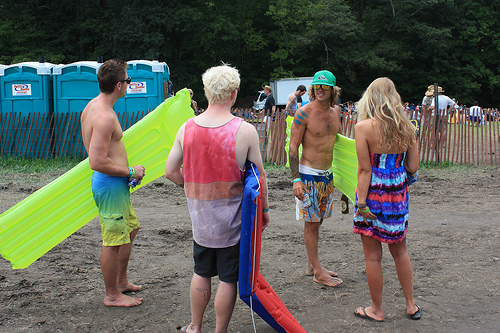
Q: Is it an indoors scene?
A: Yes, it is indoors.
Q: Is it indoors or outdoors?
A: It is indoors.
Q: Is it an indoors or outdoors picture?
A: It is indoors.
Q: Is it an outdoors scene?
A: No, it is indoors.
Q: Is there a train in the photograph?
A: No, there are no trains.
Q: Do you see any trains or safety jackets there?
A: No, there are no trains or safety jackets.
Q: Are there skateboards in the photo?
A: No, there are no skateboards.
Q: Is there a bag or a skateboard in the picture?
A: No, there are no skateboards or bags.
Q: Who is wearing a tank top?
A: The guy is wearing a tank top.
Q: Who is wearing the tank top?
A: The guy is wearing a tank top.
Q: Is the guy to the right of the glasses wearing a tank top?
A: Yes, the guy is wearing a tank top.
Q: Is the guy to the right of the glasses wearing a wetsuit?
A: No, the guy is wearing a tank top.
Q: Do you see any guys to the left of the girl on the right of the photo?
A: Yes, there is a guy to the left of the girl.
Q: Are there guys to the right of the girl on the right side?
A: No, the guy is to the left of the girl.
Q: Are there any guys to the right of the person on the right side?
A: No, the guy is to the left of the girl.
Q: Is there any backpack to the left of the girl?
A: No, there is a guy to the left of the girl.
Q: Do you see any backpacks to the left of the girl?
A: No, there is a guy to the left of the girl.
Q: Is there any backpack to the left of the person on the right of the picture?
A: No, there is a guy to the left of the girl.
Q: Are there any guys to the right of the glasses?
A: Yes, there is a guy to the right of the glasses.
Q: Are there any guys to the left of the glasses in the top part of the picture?
A: No, the guy is to the right of the glasses.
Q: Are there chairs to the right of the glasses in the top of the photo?
A: No, there is a guy to the right of the glasses.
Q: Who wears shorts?
A: The guy wears shorts.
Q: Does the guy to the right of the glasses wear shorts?
A: Yes, the guy wears shorts.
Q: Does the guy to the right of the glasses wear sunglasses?
A: No, the guy wears shorts.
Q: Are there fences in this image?
A: Yes, there is a fence.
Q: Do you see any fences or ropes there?
A: Yes, there is a fence.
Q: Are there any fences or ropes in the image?
A: Yes, there is a fence.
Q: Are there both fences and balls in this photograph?
A: No, there is a fence but no balls.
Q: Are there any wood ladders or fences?
A: Yes, there is a wood fence.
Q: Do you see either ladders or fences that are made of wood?
A: Yes, the fence is made of wood.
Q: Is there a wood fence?
A: Yes, there is a wood fence.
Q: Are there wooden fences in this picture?
A: Yes, there is a wood fence.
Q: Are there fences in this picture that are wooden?
A: Yes, there is a fence that is wooden.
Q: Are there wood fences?
A: Yes, there is a fence that is made of wood.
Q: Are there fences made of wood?
A: Yes, there is a fence that is made of wood.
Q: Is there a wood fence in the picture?
A: Yes, there is a fence that is made of wood.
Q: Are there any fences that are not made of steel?
A: Yes, there is a fence that is made of wood.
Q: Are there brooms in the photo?
A: No, there are no brooms.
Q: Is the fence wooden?
A: Yes, the fence is wooden.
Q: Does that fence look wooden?
A: Yes, the fence is wooden.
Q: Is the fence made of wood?
A: Yes, the fence is made of wood.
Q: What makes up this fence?
A: The fence is made of wood.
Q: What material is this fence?
A: The fence is made of wood.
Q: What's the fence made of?
A: The fence is made of wood.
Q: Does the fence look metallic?
A: No, the fence is wooden.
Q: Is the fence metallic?
A: No, the fence is wooden.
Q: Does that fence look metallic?
A: No, the fence is wooden.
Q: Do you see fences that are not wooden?
A: No, there is a fence but it is wooden.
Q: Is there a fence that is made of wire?
A: No, there is a fence but it is made of wood.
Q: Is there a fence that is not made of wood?
A: No, there is a fence but it is made of wood.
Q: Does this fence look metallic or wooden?
A: The fence is wooden.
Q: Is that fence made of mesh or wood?
A: The fence is made of wood.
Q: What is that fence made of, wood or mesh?
A: The fence is made of wood.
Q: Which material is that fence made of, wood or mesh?
A: The fence is made of wood.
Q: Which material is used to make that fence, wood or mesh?
A: The fence is made of wood.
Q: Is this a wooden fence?
A: Yes, this is a wooden fence.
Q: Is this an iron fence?
A: No, this is a wooden fence.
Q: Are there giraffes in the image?
A: No, there are no giraffes.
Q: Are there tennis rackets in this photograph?
A: No, there are no tennis rackets.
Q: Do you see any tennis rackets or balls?
A: No, there are no tennis rackets or balls.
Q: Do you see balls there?
A: No, there are no balls.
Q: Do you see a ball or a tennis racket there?
A: No, there are no balls or rackets.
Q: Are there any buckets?
A: No, there are no buckets.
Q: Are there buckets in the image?
A: No, there are no buckets.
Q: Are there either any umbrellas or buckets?
A: No, there are no buckets or umbrellas.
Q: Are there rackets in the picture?
A: No, there are no rackets.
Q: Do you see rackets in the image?
A: No, there are no rackets.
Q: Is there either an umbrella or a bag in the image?
A: No, there are no bags or umbrellas.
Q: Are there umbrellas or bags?
A: No, there are no bags or umbrellas.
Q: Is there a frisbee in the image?
A: No, there are no frisbees.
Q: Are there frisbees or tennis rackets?
A: No, there are no frisbees or tennis rackets.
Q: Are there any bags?
A: No, there are no bags.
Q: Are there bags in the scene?
A: No, there are no bags.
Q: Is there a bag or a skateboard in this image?
A: No, there are no bags or skateboards.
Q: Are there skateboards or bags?
A: No, there are no bags or skateboards.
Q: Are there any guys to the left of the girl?
A: Yes, there is a guy to the left of the girl.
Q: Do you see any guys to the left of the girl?
A: Yes, there is a guy to the left of the girl.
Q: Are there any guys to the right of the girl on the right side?
A: No, the guy is to the left of the girl.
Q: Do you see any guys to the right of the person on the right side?
A: No, the guy is to the left of the girl.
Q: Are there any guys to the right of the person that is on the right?
A: No, the guy is to the left of the girl.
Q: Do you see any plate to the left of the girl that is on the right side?
A: No, there is a guy to the left of the girl.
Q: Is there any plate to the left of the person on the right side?
A: No, there is a guy to the left of the girl.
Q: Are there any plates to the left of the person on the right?
A: No, there is a guy to the left of the girl.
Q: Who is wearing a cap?
A: The guy is wearing a cap.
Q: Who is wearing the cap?
A: The guy is wearing a cap.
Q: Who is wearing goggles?
A: The guy is wearing goggles.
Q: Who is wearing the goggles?
A: The guy is wearing goggles.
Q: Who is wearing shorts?
A: The guy is wearing shorts.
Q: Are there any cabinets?
A: No, there are no cabinets.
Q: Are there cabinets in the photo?
A: No, there are no cabinets.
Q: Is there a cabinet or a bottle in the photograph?
A: No, there are no cabinets or bottles.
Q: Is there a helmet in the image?
A: No, there are no helmets.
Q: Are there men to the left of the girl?
A: Yes, there is a man to the left of the girl.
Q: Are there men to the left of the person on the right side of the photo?
A: Yes, there is a man to the left of the girl.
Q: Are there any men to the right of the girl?
A: No, the man is to the left of the girl.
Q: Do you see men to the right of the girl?
A: No, the man is to the left of the girl.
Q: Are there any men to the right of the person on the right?
A: No, the man is to the left of the girl.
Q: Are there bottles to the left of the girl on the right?
A: No, there is a man to the left of the girl.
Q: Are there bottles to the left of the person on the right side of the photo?
A: No, there is a man to the left of the girl.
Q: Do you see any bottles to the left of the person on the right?
A: No, there is a man to the left of the girl.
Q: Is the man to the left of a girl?
A: Yes, the man is to the left of a girl.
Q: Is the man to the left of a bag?
A: No, the man is to the left of a girl.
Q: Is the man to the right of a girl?
A: No, the man is to the left of a girl.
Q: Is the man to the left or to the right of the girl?
A: The man is to the left of the girl.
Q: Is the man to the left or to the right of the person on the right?
A: The man is to the left of the girl.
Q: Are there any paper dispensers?
A: No, there are no paper dispensers.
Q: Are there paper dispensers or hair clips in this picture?
A: No, there are no paper dispensers or hair clips.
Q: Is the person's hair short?
A: No, the hair is long.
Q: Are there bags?
A: No, there are no bags.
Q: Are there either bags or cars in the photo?
A: No, there are no bags or cars.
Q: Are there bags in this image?
A: No, there are no bags.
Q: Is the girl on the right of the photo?
A: Yes, the girl is on the right of the image.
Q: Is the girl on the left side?
A: No, the girl is on the right of the image.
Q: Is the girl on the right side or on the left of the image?
A: The girl is on the right of the image.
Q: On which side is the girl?
A: The girl is on the right of the image.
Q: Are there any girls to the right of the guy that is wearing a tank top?
A: Yes, there is a girl to the right of the guy.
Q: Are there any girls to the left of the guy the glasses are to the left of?
A: No, the girl is to the right of the guy.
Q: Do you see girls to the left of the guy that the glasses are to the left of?
A: No, the girl is to the right of the guy.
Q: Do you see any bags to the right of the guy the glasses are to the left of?
A: No, there is a girl to the right of the guy.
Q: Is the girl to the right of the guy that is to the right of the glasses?
A: Yes, the girl is to the right of the guy.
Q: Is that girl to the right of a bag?
A: No, the girl is to the right of the guy.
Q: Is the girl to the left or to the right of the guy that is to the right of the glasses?
A: The girl is to the right of the guy.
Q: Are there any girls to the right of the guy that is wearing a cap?
A: Yes, there is a girl to the right of the guy.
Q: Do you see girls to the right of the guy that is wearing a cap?
A: Yes, there is a girl to the right of the guy.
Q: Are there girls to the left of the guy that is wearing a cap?
A: No, the girl is to the right of the guy.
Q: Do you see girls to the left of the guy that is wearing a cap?
A: No, the girl is to the right of the guy.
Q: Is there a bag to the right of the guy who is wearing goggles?
A: No, there is a girl to the right of the guy.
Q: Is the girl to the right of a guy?
A: Yes, the girl is to the right of a guy.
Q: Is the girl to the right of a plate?
A: No, the girl is to the right of a guy.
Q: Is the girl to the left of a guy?
A: No, the girl is to the right of a guy.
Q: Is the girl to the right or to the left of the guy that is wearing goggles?
A: The girl is to the right of the guy.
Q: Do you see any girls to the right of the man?
A: Yes, there is a girl to the right of the man.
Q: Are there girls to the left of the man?
A: No, the girl is to the right of the man.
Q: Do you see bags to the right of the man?
A: No, there is a girl to the right of the man.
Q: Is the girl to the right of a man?
A: Yes, the girl is to the right of a man.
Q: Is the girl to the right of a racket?
A: No, the girl is to the right of a man.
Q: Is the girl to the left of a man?
A: No, the girl is to the right of a man.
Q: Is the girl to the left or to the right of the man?
A: The girl is to the right of the man.